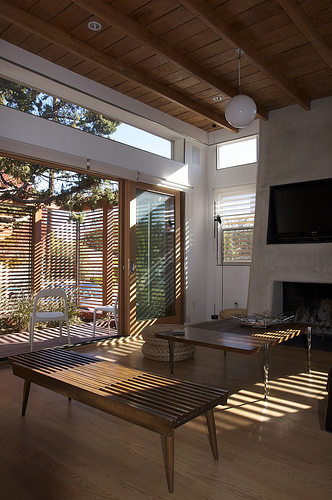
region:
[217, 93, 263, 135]
Hanging light from ceiling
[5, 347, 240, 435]
Brown wooden bench seat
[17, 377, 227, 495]
Brown wooden bench legs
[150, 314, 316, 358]
Brown wooden table top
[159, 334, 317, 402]
Brown wooden table legs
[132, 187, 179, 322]
Glass pane on door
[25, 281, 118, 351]
White chairs sitting outside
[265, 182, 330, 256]
Black TV in wall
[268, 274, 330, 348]
Fireplace in wall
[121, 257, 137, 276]
Door handle on wooden door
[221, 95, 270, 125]
the globe is hanging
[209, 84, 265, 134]
the globe is white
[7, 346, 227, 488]
the bench is wooden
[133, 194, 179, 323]
the door is glass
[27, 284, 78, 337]
the chair is white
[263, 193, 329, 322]
the television is above the fireplace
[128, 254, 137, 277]
the handle is black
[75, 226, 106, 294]
the blinds are open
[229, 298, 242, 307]
the socket is on the wall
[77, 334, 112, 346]
the door rail is black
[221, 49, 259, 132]
a long ceiling light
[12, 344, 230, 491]
a long wooden table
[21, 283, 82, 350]
a white outdoor chair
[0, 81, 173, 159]
a long living room window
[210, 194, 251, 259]
white window blinds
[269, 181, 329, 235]
a large black t.v.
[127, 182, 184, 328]
a large brown door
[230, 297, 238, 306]
a white wall outlet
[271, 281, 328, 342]
a woodburning fireplace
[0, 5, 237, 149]
a long brown wooden beam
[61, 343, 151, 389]
shadow cast on the floor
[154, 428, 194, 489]
brown legs on the table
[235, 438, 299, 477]
brown hard wood floot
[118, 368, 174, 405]
lines on top of the table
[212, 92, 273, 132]
large white bulb in ceiling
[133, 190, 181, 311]
large pane of green grass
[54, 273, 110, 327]
red trunk parked in spot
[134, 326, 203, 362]
wicker basket on floor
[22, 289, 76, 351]
white plastic chair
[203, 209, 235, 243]
rounded black lock on the door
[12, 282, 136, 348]
two white chairs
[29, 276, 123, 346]
chairs are on the patio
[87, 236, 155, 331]
door to the patio is open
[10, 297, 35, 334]
plants in front of chairs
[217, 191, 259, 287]
blinds are open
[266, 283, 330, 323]
opening on the fireplace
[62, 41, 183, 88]
exposed beams on the ceiling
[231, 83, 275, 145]
globe light hanging from the ceiling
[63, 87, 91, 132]
long rectangular window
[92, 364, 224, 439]
coffee table in living room